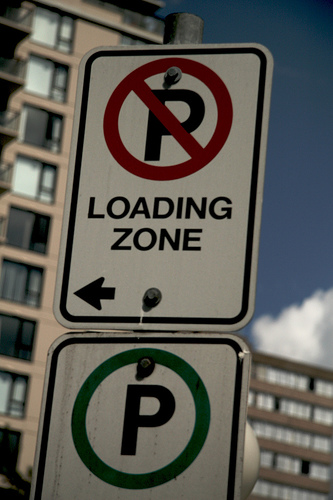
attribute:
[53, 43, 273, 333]
sign — higher, rectangular, white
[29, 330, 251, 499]
sign — lower, rectangular, lowest, white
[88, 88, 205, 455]
letters — black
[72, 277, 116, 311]
arrow — pointing, black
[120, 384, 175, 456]
p — black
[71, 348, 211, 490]
circle — green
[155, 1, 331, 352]
sky — blue, bright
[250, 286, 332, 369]
cloud — white, large, puffy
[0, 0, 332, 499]
building — big, brown, tall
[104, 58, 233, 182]
circle — red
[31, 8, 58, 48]
curtain — window, long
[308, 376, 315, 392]
window — opened